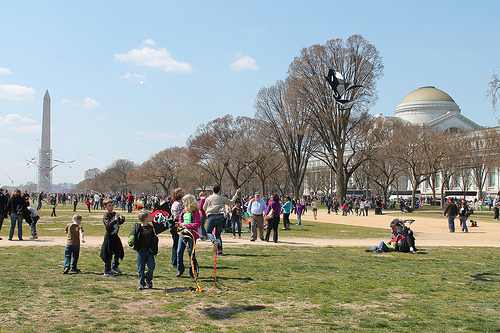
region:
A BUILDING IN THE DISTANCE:
[35, 88, 70, 206]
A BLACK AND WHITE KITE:
[314, 58, 369, 118]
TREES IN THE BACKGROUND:
[178, 78, 298, 198]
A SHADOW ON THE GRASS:
[188, 296, 280, 326]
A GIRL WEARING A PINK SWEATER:
[172, 193, 206, 282]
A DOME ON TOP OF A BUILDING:
[389, 82, 471, 121]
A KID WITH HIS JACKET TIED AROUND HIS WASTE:
[96, 191, 134, 283]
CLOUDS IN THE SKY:
[84, 28, 284, 94]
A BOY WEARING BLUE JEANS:
[57, 211, 94, 283]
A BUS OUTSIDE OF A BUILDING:
[435, 183, 498, 203]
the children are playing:
[37, 185, 270, 330]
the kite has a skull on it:
[146, 206, 261, 316]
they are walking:
[433, 187, 485, 261]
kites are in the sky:
[15, 152, 110, 222]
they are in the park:
[12, 151, 367, 332]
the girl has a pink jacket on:
[173, 175, 240, 298]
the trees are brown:
[83, 146, 409, 312]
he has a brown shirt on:
[63, 211, 107, 321]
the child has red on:
[80, 195, 109, 212]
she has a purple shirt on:
[261, 185, 311, 315]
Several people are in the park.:
[2, 150, 484, 287]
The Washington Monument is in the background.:
[22, 81, 69, 206]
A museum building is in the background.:
[277, 76, 497, 216]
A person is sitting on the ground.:
[360, 208, 423, 263]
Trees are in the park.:
[71, 32, 386, 209]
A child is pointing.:
[117, 197, 187, 304]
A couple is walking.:
[437, 191, 479, 240]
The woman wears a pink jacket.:
[171, 189, 206, 241]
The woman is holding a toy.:
[148, 207, 229, 254]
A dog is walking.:
[466, 211, 482, 231]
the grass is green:
[260, 246, 360, 306]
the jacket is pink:
[171, 196, 213, 236]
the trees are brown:
[210, 95, 312, 165]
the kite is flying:
[311, 57, 368, 112]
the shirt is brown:
[62, 222, 82, 248]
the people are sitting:
[367, 219, 432, 268]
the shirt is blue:
[246, 200, 273, 216]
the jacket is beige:
[199, 193, 239, 223]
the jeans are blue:
[132, 250, 165, 287]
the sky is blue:
[49, 31, 114, 84]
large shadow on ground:
[182, 295, 295, 319]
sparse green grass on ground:
[102, 286, 262, 319]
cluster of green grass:
[292, 239, 368, 280]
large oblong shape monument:
[29, 59, 68, 181]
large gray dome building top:
[390, 74, 466, 109]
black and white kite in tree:
[307, 52, 375, 124]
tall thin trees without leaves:
[271, 62, 326, 217]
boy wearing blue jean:
[50, 237, 91, 272]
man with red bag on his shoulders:
[244, 191, 274, 216]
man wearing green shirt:
[275, 192, 302, 217]